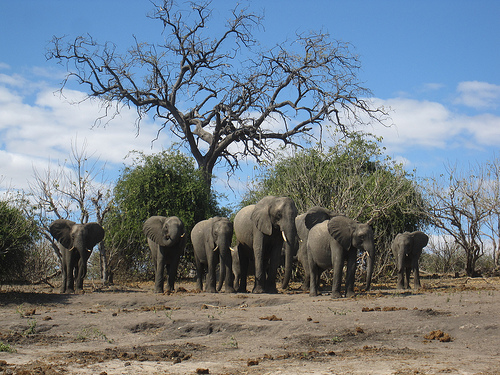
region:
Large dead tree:
[39, 6, 359, 168]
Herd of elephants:
[43, 198, 441, 294]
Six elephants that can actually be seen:
[43, 198, 430, 300]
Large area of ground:
[5, 277, 490, 362]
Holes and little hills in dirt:
[36, 290, 342, 360]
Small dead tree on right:
[420, 170, 495, 265]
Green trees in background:
[105, 135, 415, 220]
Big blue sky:
[10, 50, 495, 180]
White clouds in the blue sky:
[4, 83, 149, 192]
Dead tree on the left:
[27, 135, 117, 296]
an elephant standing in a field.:
[372, 193, 455, 310]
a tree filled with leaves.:
[235, 131, 446, 290]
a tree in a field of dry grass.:
[59, 3, 388, 284]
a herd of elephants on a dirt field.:
[42, 189, 470, 339]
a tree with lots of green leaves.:
[222, 115, 439, 290]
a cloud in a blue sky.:
[288, 62, 491, 149]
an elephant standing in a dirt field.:
[50, 197, 118, 297]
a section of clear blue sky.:
[382, 24, 452, 50]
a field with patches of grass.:
[0, 283, 498, 373]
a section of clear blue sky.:
[398, 21, 448, 63]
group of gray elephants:
[46, 195, 449, 295]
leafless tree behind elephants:
[45, 12, 374, 144]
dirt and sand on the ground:
[182, 312, 480, 370]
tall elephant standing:
[230, 197, 297, 292]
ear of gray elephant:
[329, 214, 355, 245]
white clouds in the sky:
[380, 85, 485, 162]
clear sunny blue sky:
[20, 10, 120, 26]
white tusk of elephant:
[280, 230, 286, 240]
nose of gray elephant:
[358, 245, 375, 291]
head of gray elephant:
[162, 220, 184, 243]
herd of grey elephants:
[127, 197, 439, 312]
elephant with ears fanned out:
[42, 213, 108, 291]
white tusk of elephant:
[275, 224, 292, 245]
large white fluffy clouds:
[10, 81, 127, 177]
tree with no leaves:
[50, 12, 370, 154]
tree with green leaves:
[114, 149, 191, 212]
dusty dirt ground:
[105, 299, 369, 365]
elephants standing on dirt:
[127, 182, 395, 302]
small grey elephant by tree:
[383, 226, 435, 295]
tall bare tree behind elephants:
[58, 16, 350, 136]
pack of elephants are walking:
[45, 183, 412, 318]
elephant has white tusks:
[256, 210, 304, 253]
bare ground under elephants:
[115, 273, 343, 367]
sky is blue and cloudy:
[382, 18, 462, 76]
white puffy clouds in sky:
[361, 98, 471, 163]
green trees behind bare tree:
[165, 136, 337, 220]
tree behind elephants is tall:
[80, 18, 317, 194]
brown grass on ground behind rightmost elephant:
[415, 245, 492, 309]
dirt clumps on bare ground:
[292, 291, 427, 359]